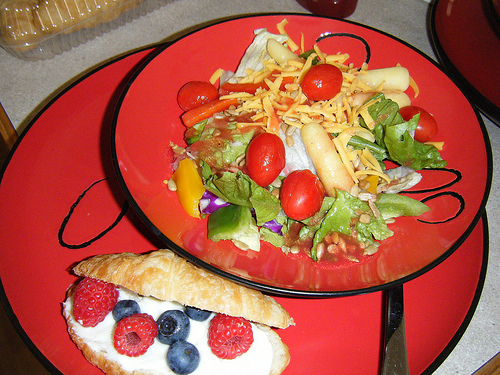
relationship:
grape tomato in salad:
[279, 168, 326, 220] [110, 12, 492, 297]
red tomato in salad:
[244, 130, 287, 187] [165, 25, 441, 252]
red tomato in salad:
[174, 79, 220, 112] [191, 28, 443, 252]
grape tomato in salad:
[301, 61, 345, 101] [165, 25, 441, 252]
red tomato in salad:
[394, 104, 439, 143] [165, 25, 441, 252]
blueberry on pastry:
[184, 300, 211, 325] [39, 241, 299, 374]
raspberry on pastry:
[72, 275, 117, 327] [39, 241, 299, 374]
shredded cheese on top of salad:
[208, 17, 418, 184] [165, 25, 441, 252]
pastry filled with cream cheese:
[58, 249, 302, 374] [248, 339, 280, 373]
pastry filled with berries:
[58, 249, 302, 374] [112, 303, 197, 352]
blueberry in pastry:
[155, 299, 201, 374] [39, 241, 299, 374]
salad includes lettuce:
[165, 25, 441, 252] [368, 96, 446, 173]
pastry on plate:
[58, 249, 302, 374] [109, 14, 487, 297]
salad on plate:
[165, 25, 441, 252] [109, 14, 487, 297]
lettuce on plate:
[317, 189, 423, 254] [109, 14, 487, 297]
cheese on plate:
[304, 101, 378, 130] [109, 14, 487, 297]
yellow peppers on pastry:
[165, 137, 215, 227] [58, 249, 302, 374]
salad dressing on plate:
[287, 132, 303, 164] [109, 14, 487, 297]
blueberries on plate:
[205, 313, 255, 362] [1, 37, 492, 374]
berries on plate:
[112, 312, 159, 357] [1, 37, 492, 374]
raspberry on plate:
[72, 275, 117, 327] [1, 37, 492, 374]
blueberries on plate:
[110, 292, 222, 373] [1, 37, 492, 374]